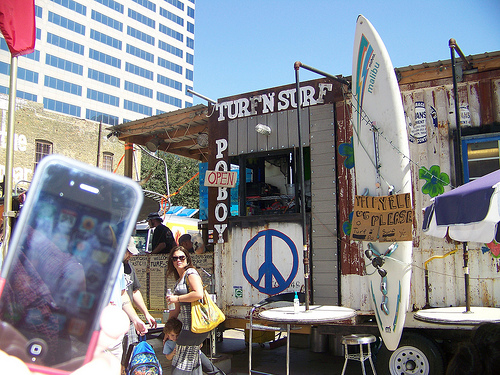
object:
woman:
[163, 245, 226, 375]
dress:
[169, 269, 211, 374]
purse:
[186, 274, 227, 335]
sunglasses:
[170, 255, 187, 261]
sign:
[215, 83, 334, 122]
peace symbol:
[241, 228, 299, 297]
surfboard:
[347, 13, 417, 355]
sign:
[204, 171, 238, 188]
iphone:
[0, 155, 145, 375]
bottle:
[166, 287, 176, 311]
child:
[162, 316, 193, 375]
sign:
[211, 139, 231, 243]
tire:
[370, 330, 447, 375]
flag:
[0, 1, 33, 57]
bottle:
[293, 291, 301, 317]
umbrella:
[420, 167, 498, 244]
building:
[0, 0, 200, 129]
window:
[186, 34, 197, 50]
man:
[147, 213, 175, 255]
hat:
[146, 212, 161, 225]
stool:
[340, 333, 379, 375]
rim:
[387, 346, 430, 375]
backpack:
[121, 332, 162, 374]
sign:
[352, 193, 416, 242]